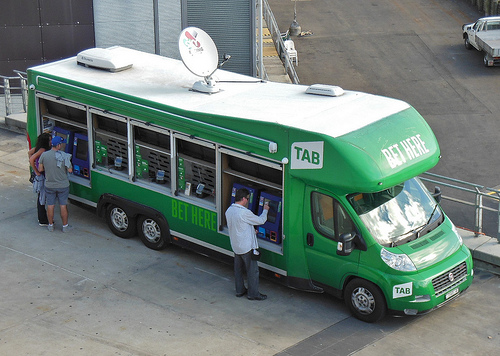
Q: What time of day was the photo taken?
A: Daytime.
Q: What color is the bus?
A: Green.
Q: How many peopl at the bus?
A: Three.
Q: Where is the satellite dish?
A: On top of the bus.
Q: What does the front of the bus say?
A: Bet Here.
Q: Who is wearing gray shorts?
A: The man on the left.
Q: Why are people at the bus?
A: To place bets.